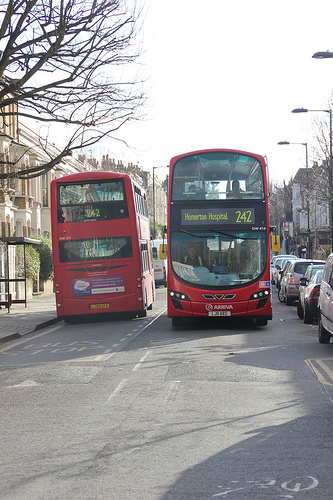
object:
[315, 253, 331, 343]
car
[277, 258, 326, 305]
car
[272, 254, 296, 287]
car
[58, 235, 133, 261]
bottom window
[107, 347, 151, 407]
lines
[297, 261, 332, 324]
cars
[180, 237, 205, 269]
driver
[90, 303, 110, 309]
license plate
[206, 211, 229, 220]
yellow word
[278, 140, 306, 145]
street lamp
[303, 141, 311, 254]
pole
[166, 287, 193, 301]
lights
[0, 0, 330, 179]
sky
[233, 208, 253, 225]
242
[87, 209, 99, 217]
242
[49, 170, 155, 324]
bus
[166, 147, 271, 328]
bus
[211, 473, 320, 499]
mark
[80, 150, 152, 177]
chimneys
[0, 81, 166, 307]
building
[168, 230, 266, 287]
windshield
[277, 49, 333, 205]
lights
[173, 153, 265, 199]
window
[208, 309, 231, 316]
license plate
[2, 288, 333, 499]
road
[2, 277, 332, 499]
pavement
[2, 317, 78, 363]
curb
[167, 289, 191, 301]
lump